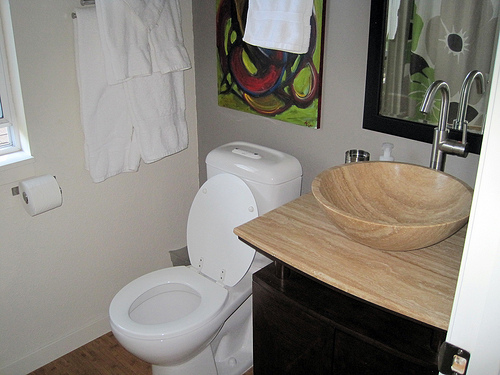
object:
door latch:
[437, 342, 470, 375]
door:
[436, 33, 500, 375]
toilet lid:
[186, 173, 260, 287]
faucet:
[419, 70, 485, 172]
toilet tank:
[204, 141, 301, 262]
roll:
[19, 174, 63, 217]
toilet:
[108, 141, 303, 375]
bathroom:
[0, 0, 500, 375]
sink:
[311, 161, 474, 252]